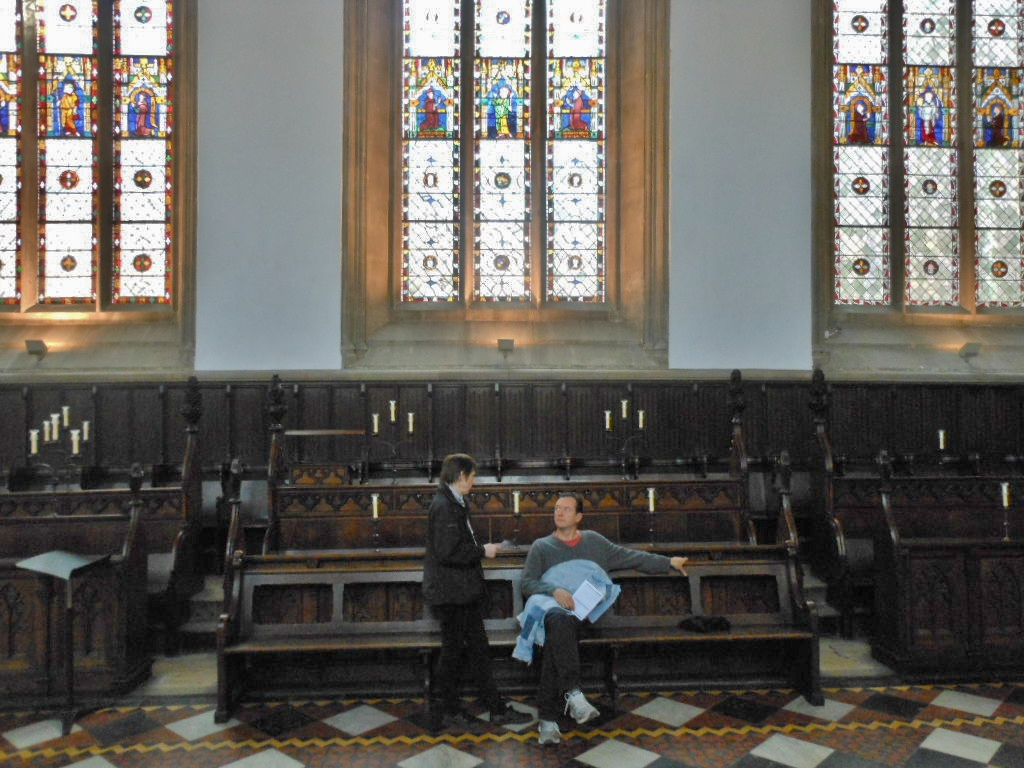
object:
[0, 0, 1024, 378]
wall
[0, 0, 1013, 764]
building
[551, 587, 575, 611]
man's hand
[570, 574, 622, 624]
paper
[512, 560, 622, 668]
jacket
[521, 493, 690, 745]
man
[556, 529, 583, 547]
undershirt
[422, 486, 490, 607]
jacket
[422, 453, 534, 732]
man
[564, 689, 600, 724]
shoe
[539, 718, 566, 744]
shoe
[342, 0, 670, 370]
window